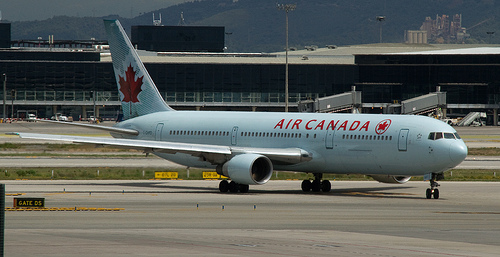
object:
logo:
[270, 116, 396, 135]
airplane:
[3, 18, 471, 203]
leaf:
[114, 62, 153, 115]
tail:
[20, 17, 184, 144]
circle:
[372, 117, 394, 136]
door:
[321, 127, 339, 151]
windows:
[424, 129, 467, 141]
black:
[12, 196, 49, 209]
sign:
[10, 194, 47, 211]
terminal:
[35, 18, 177, 155]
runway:
[0, 179, 500, 257]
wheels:
[296, 177, 336, 194]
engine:
[220, 151, 275, 188]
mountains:
[0, 0, 498, 52]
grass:
[0, 164, 208, 181]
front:
[387, 108, 473, 178]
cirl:
[371, 116, 396, 136]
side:
[106, 112, 472, 171]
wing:
[1, 130, 314, 166]